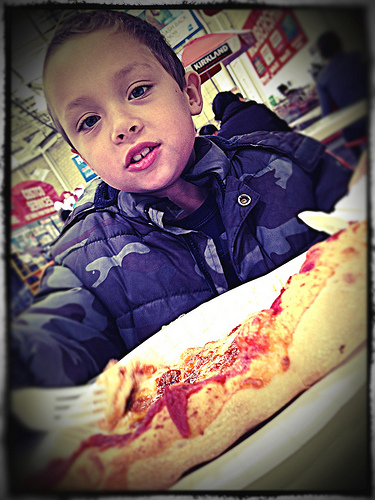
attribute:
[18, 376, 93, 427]
fork — plastic, white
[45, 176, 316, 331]
jacket — blue, camo, camouflage, black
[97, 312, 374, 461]
pizza — large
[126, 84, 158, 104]
eye — brown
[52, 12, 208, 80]
hair — brown, groomed, tidy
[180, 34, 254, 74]
umbrella — open